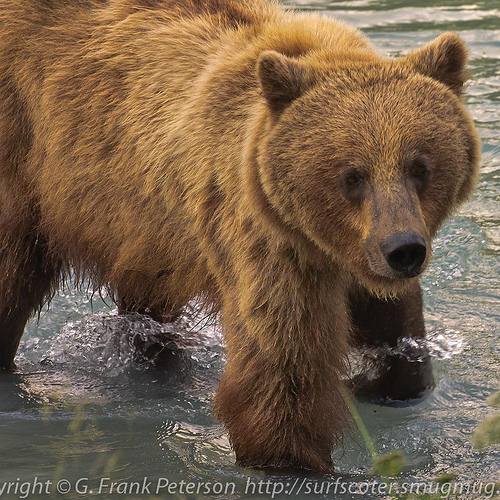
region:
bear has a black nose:
[380, 233, 475, 279]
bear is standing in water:
[34, 169, 496, 473]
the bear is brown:
[65, 71, 490, 316]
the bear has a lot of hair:
[68, 100, 320, 294]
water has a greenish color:
[382, 5, 497, 78]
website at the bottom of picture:
[8, 475, 488, 496]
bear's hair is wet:
[22, 235, 193, 330]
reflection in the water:
[43, 382, 144, 480]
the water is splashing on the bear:
[350, 320, 465, 406]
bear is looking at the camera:
[251, 105, 497, 308]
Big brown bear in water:
[50, 0, 479, 470]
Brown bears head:
[252, 33, 484, 288]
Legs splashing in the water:
[0, 315, 450, 479]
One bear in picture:
[0, 3, 482, 475]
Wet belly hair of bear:
[11, 197, 252, 342]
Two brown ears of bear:
[255, 30, 475, 105]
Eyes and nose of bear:
[340, 157, 440, 280]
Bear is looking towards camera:
[254, 21, 489, 315]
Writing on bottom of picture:
[0, 470, 496, 499]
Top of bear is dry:
[0, 0, 485, 280]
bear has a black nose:
[380, 234, 422, 282]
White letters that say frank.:
[92, 468, 157, 498]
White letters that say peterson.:
[148, 471, 243, 498]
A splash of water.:
[15, 316, 195, 468]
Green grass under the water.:
[19, 381, 191, 481]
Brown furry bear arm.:
[225, 285, 357, 499]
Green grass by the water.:
[305, 375, 495, 498]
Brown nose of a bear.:
[315, 209, 450, 280]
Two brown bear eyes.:
[260, 137, 455, 212]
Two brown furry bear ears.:
[183, 19, 495, 131]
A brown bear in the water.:
[1, 4, 476, 416]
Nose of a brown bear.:
[372, 161, 427, 274]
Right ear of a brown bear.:
[258, 50, 305, 109]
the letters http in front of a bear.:
[243, 475, 284, 499]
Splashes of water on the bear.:
[65, 313, 192, 371]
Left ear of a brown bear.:
[419, 31, 469, 93]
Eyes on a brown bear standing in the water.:
[336, 158, 430, 185]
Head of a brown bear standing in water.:
[257, 29, 479, 281]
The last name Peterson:
[157, 477, 236, 497]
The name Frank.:
[99, 474, 152, 494]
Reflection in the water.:
[37, 400, 138, 469]